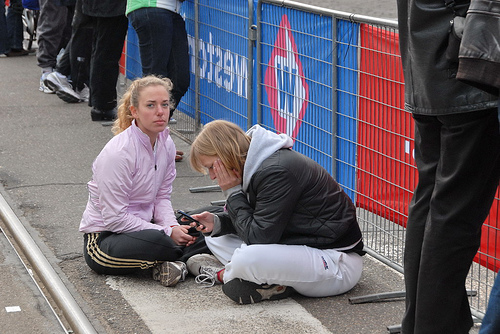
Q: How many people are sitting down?
A: Two.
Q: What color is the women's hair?
A: Blonde.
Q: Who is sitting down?
A: Two women.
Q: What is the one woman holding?
A: A cell phone.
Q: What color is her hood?
A: White.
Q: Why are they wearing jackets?
A: It's cold outside.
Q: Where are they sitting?
A: On the sidewalk.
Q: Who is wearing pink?
A: The woman on the left.